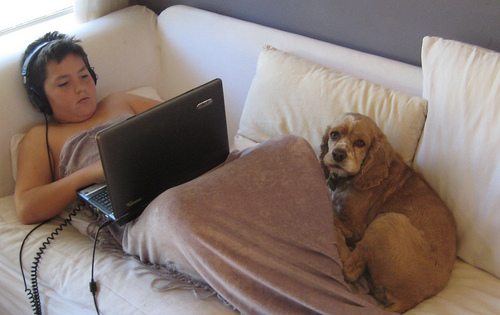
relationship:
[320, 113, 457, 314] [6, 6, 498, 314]
dog on couch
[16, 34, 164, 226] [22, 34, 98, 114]
boy has headphone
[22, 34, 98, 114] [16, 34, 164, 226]
headphone on boy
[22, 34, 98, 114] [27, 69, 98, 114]
headphone on ears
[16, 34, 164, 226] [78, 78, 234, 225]
boy using laptop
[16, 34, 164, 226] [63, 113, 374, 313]
boy has blanket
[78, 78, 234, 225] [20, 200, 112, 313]
laptop has cords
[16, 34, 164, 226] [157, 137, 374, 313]
boy has legs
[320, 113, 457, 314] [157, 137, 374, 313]
dog by legs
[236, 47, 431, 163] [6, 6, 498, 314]
pillow on couch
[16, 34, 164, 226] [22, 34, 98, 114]
boy wearing headphone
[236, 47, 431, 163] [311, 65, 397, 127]
pillow has wrinkles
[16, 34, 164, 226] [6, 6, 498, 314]
boy on couch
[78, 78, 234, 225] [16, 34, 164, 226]
laptop on boy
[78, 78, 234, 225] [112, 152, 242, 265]
laptop on lap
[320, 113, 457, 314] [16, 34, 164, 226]
dog next to boy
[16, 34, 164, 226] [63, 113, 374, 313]
boy under blanket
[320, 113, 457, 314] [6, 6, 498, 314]
dog laying on couch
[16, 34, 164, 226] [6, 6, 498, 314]
boy laying on couch